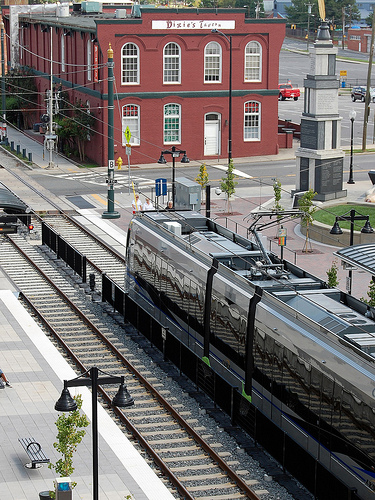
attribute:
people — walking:
[127, 191, 155, 212]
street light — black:
[54, 365, 131, 498]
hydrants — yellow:
[113, 156, 126, 167]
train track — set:
[3, 233, 251, 498]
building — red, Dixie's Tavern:
[17, 1, 284, 164]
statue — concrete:
[291, 0, 346, 201]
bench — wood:
[18, 427, 57, 467]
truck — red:
[268, 66, 333, 94]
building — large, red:
[19, 7, 310, 177]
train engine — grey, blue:
[250, 279, 374, 494]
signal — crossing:
[38, 83, 62, 170]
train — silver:
[124, 197, 374, 400]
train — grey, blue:
[122, 205, 371, 496]